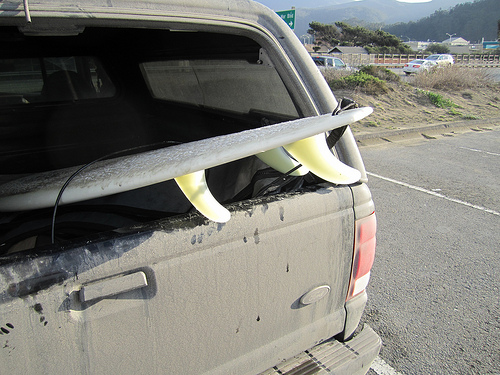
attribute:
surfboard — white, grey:
[0, 97, 373, 225]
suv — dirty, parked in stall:
[1, 1, 384, 373]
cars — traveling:
[310, 52, 456, 77]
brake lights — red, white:
[353, 209, 379, 275]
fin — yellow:
[283, 132, 362, 190]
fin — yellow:
[173, 171, 234, 225]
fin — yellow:
[255, 148, 311, 179]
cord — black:
[31, 137, 183, 244]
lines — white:
[361, 146, 500, 219]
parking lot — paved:
[2, 3, 499, 375]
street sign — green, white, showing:
[273, 8, 297, 30]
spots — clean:
[252, 230, 262, 245]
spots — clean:
[278, 204, 286, 222]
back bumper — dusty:
[240, 319, 383, 374]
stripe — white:
[448, 137, 499, 160]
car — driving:
[312, 53, 360, 75]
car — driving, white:
[402, 56, 438, 77]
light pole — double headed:
[444, 30, 458, 46]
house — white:
[307, 43, 368, 55]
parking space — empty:
[356, 138, 499, 212]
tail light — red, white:
[346, 208, 378, 301]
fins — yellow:
[164, 133, 363, 225]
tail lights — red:
[402, 61, 420, 70]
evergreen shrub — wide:
[307, 18, 450, 56]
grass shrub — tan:
[412, 65, 476, 92]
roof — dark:
[328, 42, 366, 54]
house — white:
[444, 35, 472, 47]